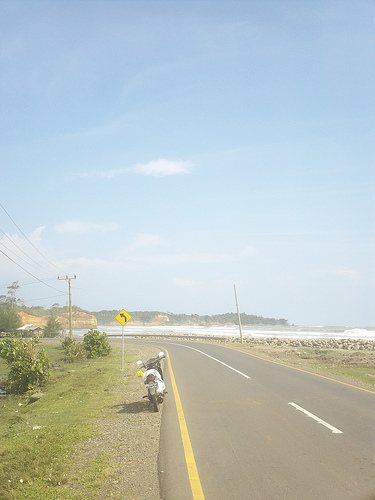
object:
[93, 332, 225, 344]
rails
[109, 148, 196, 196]
cloud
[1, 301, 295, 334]
low hills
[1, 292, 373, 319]
horizon line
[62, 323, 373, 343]
waters edge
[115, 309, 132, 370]
signpost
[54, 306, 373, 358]
lake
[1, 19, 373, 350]
background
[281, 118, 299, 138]
ground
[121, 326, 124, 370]
pole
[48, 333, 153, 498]
ground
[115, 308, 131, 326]
road sign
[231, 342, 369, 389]
shoulder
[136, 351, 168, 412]
motorbike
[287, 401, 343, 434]
line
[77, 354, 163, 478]
gravel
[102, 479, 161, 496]
dirt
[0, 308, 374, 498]
landscape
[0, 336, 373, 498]
highway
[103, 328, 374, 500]
lane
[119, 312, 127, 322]
arrow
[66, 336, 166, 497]
shoulder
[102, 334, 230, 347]
guard rail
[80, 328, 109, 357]
bush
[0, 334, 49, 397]
bush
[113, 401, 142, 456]
dirt